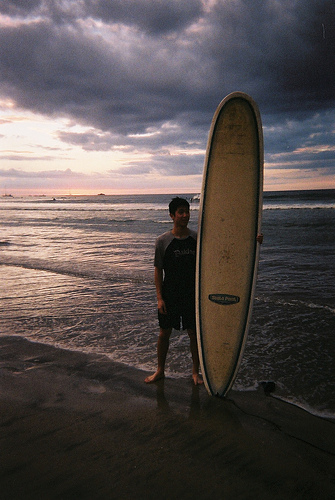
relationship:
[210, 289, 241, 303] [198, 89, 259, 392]
logo on surfboard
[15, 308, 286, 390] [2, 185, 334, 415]
sea foam on moving water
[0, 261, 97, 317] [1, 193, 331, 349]
light reflection on water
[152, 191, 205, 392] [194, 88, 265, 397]
man with board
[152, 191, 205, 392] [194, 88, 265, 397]
man beside board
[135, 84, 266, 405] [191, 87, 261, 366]
hand holding surboard